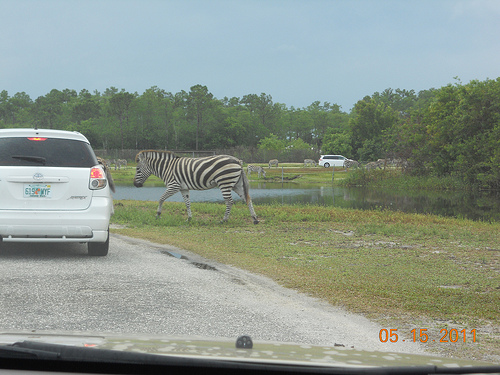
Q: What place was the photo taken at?
A: It was taken at the road.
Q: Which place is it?
A: It is a road.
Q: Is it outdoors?
A: Yes, it is outdoors.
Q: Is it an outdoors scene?
A: Yes, it is outdoors.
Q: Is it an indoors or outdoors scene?
A: It is outdoors.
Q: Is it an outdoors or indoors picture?
A: It is outdoors.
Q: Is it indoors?
A: No, it is outdoors.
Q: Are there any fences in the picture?
A: No, there are no fences.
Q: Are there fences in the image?
A: No, there are no fences.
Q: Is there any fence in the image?
A: No, there are no fences.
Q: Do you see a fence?
A: No, there are no fences.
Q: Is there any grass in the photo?
A: Yes, there is grass.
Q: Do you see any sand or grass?
A: Yes, there is grass.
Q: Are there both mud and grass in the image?
A: No, there is grass but no mud.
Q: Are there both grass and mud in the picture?
A: No, there is grass but no mud.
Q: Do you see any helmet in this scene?
A: No, there are no helmets.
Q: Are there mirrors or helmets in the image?
A: No, there are no helmets or mirrors.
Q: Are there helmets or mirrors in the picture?
A: No, there are no helmets or mirrors.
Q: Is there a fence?
A: No, there are no fences.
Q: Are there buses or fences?
A: No, there are no fences or buses.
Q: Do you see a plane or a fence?
A: No, there are no fences or airplanes.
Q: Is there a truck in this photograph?
A: No, there are no trucks.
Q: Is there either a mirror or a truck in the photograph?
A: No, there are no trucks or mirrors.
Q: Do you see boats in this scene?
A: No, there are no boats.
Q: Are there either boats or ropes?
A: No, there are no boats or ropes.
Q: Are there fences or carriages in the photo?
A: No, there are no fences or carriages.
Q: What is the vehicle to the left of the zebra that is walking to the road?
A: The vehicle is a car.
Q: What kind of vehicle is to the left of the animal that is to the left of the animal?
A: The vehicle is a car.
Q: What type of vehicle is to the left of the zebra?
A: The vehicle is a car.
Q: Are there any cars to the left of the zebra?
A: Yes, there is a car to the left of the zebra.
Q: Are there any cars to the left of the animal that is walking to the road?
A: Yes, there is a car to the left of the zebra.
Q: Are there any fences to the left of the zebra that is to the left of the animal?
A: No, there is a car to the left of the zebra.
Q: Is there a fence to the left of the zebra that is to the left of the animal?
A: No, there is a car to the left of the zebra.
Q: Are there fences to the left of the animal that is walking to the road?
A: No, there is a car to the left of the zebra.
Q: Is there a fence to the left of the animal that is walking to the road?
A: No, there is a car to the left of the zebra.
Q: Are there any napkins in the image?
A: No, there are no napkins.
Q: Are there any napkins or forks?
A: No, there are no napkins or forks.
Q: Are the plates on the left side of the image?
A: Yes, the plates are on the left of the image.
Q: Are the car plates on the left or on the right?
A: The plates are on the left of the image.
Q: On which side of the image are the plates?
A: The plates are on the left of the image.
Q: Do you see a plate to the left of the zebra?
A: Yes, there are plates to the left of the zebra.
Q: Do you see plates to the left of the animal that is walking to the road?
A: Yes, there are plates to the left of the zebra.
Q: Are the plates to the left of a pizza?
A: No, the plates are to the left of the zebra.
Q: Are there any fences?
A: No, there are no fences.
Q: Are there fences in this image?
A: No, there are no fences.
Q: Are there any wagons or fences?
A: No, there are no fences or wagons.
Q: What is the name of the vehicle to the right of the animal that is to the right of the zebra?
A: The vehicle is a car.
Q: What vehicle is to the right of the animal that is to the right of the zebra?
A: The vehicle is a car.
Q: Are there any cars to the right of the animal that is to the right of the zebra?
A: Yes, there is a car to the right of the animal.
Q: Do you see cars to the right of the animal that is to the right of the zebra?
A: Yes, there is a car to the right of the animal.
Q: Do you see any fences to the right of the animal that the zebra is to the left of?
A: No, there is a car to the right of the animal.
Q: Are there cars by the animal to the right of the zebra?
A: Yes, there is a car by the animal.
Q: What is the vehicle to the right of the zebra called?
A: The vehicle is a car.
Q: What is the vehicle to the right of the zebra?
A: The vehicle is a car.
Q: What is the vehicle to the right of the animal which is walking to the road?
A: The vehicle is a car.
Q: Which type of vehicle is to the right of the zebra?
A: The vehicle is a car.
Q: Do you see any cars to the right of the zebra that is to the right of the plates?
A: Yes, there is a car to the right of the zebra.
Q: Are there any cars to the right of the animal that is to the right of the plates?
A: Yes, there is a car to the right of the zebra.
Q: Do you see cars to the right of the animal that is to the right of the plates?
A: Yes, there is a car to the right of the zebra.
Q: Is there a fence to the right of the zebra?
A: No, there is a car to the right of the zebra.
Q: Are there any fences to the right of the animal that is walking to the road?
A: No, there is a car to the right of the zebra.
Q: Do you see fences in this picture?
A: No, there are no fences.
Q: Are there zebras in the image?
A: Yes, there is a zebra.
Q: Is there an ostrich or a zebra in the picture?
A: Yes, there is a zebra.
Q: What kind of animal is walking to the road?
A: The animal is a zebra.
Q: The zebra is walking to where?
A: The zebra is walking to the road.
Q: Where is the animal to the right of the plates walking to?
A: The zebra is walking to the road.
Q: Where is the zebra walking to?
A: The zebra is walking to the road.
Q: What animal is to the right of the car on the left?
A: The animal is a zebra.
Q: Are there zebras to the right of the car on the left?
A: Yes, there is a zebra to the right of the car.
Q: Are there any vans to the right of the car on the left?
A: No, there is a zebra to the right of the car.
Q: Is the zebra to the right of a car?
A: Yes, the zebra is to the right of a car.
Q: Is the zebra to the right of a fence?
A: No, the zebra is to the right of a car.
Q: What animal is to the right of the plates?
A: The animal is a zebra.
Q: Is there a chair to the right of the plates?
A: No, there is a zebra to the right of the plates.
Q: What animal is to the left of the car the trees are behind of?
A: The animal is a zebra.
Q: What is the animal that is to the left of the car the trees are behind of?
A: The animal is a zebra.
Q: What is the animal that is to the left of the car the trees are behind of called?
A: The animal is a zebra.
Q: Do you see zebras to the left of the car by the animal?
A: Yes, there is a zebra to the left of the car.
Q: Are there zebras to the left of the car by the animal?
A: Yes, there is a zebra to the left of the car.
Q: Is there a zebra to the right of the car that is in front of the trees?
A: No, the zebra is to the left of the car.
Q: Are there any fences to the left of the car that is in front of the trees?
A: No, there is a zebra to the left of the car.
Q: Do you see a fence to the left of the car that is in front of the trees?
A: No, there is a zebra to the left of the car.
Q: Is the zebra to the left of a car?
A: Yes, the zebra is to the left of a car.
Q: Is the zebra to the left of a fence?
A: No, the zebra is to the left of a car.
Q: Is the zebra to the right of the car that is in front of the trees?
A: No, the zebra is to the left of the car.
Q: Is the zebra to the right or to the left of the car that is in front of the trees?
A: The zebra is to the left of the car.